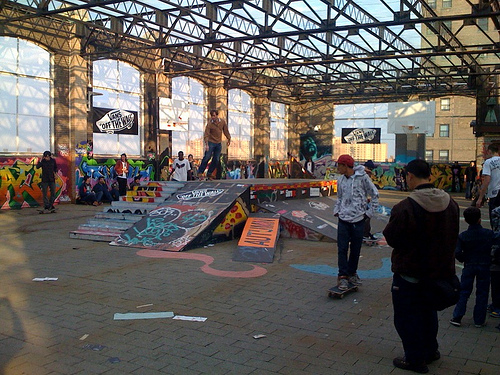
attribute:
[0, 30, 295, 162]
windows — arched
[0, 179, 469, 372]
floors — tiled